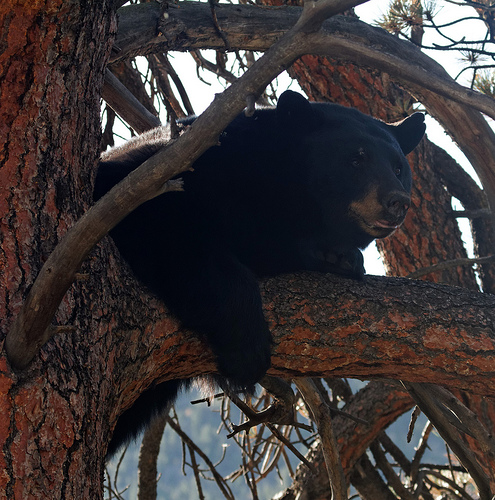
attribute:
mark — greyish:
[359, 142, 378, 166]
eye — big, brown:
[347, 148, 368, 168]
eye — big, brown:
[386, 153, 406, 176]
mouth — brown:
[354, 181, 419, 241]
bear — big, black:
[204, 141, 481, 255]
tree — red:
[0, 0, 490, 497]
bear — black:
[89, 80, 432, 402]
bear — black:
[191, 68, 461, 297]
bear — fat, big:
[92, 88, 427, 462]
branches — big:
[17, 12, 494, 396]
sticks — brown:
[24, 23, 103, 478]